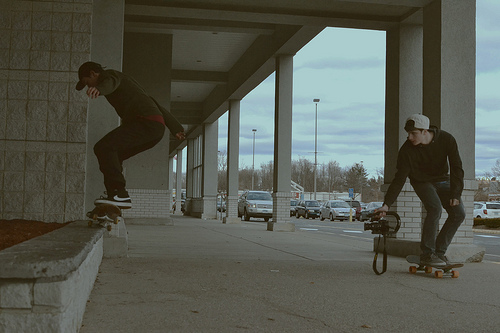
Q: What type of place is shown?
A: It is a sidewalk.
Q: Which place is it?
A: It is a sidewalk.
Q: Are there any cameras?
A: Yes, there is a camera.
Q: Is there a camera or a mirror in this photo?
A: Yes, there is a camera.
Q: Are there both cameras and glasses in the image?
A: No, there is a camera but no glasses.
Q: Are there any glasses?
A: No, there are no glasses.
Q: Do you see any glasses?
A: No, there are no glasses.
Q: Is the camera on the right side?
A: Yes, the camera is on the right of the image.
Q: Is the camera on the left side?
A: No, the camera is on the right of the image.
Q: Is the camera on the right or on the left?
A: The camera is on the right of the image.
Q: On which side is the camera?
A: The camera is on the right of the image.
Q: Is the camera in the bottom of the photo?
A: Yes, the camera is in the bottom of the image.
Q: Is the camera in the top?
A: No, the camera is in the bottom of the image.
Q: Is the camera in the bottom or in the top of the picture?
A: The camera is in the bottom of the image.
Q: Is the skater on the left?
A: Yes, the skater is on the left of the image.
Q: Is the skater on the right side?
A: No, the skater is on the left of the image.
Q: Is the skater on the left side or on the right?
A: The skater is on the left of the image.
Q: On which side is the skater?
A: The skater is on the left of the image.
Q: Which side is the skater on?
A: The skater is on the left of the image.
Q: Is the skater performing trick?
A: Yes, the skater is performing trick.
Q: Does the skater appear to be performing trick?
A: Yes, the skater is performing trick.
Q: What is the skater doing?
A: The skater is performing trick.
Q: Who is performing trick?
A: The skater is performing trick.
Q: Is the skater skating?
A: No, the skater is performing trick.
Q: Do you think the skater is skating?
A: No, the skater is performing trick.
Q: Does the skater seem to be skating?
A: No, the skater is performing trick.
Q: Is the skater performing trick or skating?
A: The skater is performing trick.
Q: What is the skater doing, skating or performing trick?
A: The skater is performing trick.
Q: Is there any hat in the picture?
A: Yes, there is a hat.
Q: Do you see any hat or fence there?
A: Yes, there is a hat.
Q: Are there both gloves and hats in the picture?
A: No, there is a hat but no gloves.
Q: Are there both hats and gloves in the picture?
A: No, there is a hat but no gloves.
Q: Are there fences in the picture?
A: No, there are no fences.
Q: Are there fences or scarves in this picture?
A: No, there are no fences or scarves.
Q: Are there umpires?
A: No, there are no umpires.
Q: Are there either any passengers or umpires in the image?
A: No, there are no umpires or passengers.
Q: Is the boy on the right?
A: Yes, the boy is on the right of the image.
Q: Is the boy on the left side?
A: No, the boy is on the right of the image.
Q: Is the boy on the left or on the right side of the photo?
A: The boy is on the right of the image.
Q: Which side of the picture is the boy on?
A: The boy is on the right of the image.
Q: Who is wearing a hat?
A: The boy is wearing a hat.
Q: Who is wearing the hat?
A: The boy is wearing a hat.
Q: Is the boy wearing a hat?
A: Yes, the boy is wearing a hat.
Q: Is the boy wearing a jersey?
A: No, the boy is wearing a hat.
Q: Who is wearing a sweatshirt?
A: The boy is wearing a sweatshirt.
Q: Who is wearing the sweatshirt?
A: The boy is wearing a sweatshirt.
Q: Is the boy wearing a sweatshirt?
A: Yes, the boy is wearing a sweatshirt.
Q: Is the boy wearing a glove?
A: No, the boy is wearing a sweatshirt.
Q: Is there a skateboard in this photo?
A: Yes, there is a skateboard.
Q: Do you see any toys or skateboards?
A: Yes, there is a skateboard.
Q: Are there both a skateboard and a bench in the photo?
A: No, there is a skateboard but no benches.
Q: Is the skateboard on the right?
A: Yes, the skateboard is on the right of the image.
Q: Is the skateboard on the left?
A: No, the skateboard is on the right of the image.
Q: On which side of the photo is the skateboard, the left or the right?
A: The skateboard is on the right of the image.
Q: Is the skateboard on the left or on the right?
A: The skateboard is on the right of the image.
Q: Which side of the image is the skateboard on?
A: The skateboard is on the right of the image.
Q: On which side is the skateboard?
A: The skateboard is on the right of the image.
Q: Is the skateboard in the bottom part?
A: Yes, the skateboard is in the bottom of the image.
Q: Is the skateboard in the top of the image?
A: No, the skateboard is in the bottom of the image.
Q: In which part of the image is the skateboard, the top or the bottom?
A: The skateboard is in the bottom of the image.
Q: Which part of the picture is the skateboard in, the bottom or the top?
A: The skateboard is in the bottom of the image.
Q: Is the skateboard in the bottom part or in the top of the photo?
A: The skateboard is in the bottom of the image.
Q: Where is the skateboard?
A: The skateboard is on the sidewalk.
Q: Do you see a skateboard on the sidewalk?
A: Yes, there is a skateboard on the sidewalk.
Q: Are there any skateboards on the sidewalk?
A: Yes, there is a skateboard on the sidewalk.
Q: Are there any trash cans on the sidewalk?
A: No, there is a skateboard on the sidewalk.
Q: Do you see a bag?
A: No, there are no bags.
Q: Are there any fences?
A: No, there are no fences.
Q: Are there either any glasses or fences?
A: No, there are no fences or glasses.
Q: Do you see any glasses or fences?
A: No, there are no fences or glasses.